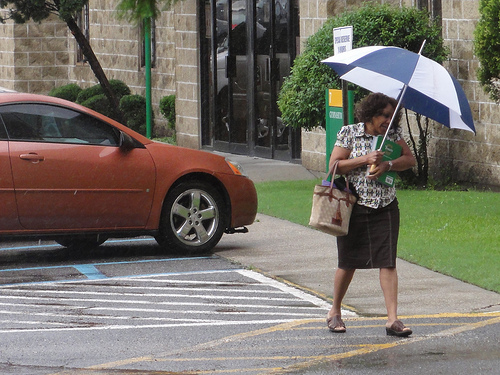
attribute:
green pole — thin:
[116, 10, 196, 187]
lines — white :
[2, 262, 359, 333]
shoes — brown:
[323, 311, 412, 337]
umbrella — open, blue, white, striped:
[317, 43, 477, 139]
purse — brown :
[306, 159, 358, 237]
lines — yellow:
[81, 308, 496, 372]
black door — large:
[204, 1, 299, 158]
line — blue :
[76, 262, 109, 279]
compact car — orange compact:
[4, 83, 263, 263]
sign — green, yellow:
[325, 89, 352, 176]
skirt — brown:
[337, 192, 410, 269]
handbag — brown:
[308, 160, 356, 235]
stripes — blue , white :
[376, 41, 451, 107]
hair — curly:
[355, 92, 401, 133]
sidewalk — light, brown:
[267, 212, 325, 314]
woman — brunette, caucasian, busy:
[327, 93, 415, 334]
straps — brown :
[321, 161, 336, 182]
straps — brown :
[328, 161, 350, 194]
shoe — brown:
[328, 313, 348, 331]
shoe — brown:
[388, 318, 412, 337]